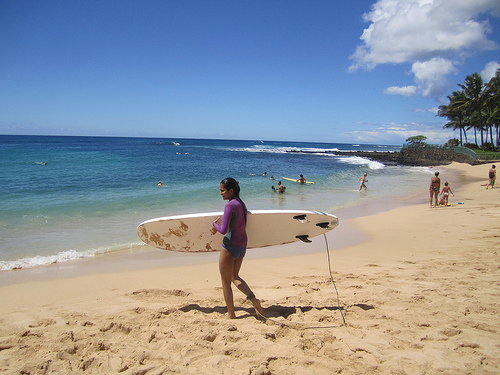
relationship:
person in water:
[151, 178, 167, 183] [25, 135, 132, 170]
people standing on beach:
[428, 171, 442, 208] [394, 205, 496, 251]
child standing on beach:
[441, 166, 458, 203] [394, 205, 496, 251]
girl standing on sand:
[211, 178, 263, 318] [2, 157, 499, 372]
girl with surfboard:
[211, 178, 263, 318] [137, 207, 340, 252]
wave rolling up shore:
[15, 225, 168, 287] [0, 150, 421, 315]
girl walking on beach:
[211, 178, 263, 318] [1, 153, 498, 373]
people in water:
[243, 158, 461, 199] [2, 139, 407, 257]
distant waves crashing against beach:
[48, 131, 104, 311] [85, 105, 180, 232]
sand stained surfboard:
[308, 245, 434, 320] [127, 197, 347, 270]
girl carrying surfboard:
[211, 178, 263, 318] [172, 203, 198, 338]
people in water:
[37, 160, 377, 200] [2, 133, 403, 266]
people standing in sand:
[430, 167, 453, 209] [18, 207, 499, 371]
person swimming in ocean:
[158, 180, 169, 187] [0, 135, 400, 272]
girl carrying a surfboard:
[211, 178, 263, 318] [137, 207, 340, 252]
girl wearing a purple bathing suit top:
[211, 178, 263, 318] [226, 193, 239, 247]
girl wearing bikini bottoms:
[211, 178, 263, 318] [221, 238, 256, 263]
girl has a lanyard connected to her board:
[222, 219, 246, 325] [136, 209, 339, 253]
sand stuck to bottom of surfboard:
[0, 226, 498, 370] [132, 191, 457, 235]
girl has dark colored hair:
[211, 178, 263, 318] [219, 146, 266, 259]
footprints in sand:
[370, 324, 395, 336] [2, 157, 499, 372]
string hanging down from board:
[306, 228, 335, 326] [133, 206, 339, 255]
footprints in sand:
[187, 273, 422, 345] [127, 306, 367, 375]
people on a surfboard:
[428, 171, 442, 208] [137, 207, 340, 252]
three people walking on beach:
[392, 157, 499, 304] [1, 153, 498, 373]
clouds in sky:
[346, 6, 499, 142] [3, 3, 497, 147]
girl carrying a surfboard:
[211, 178, 263, 318] [128, 207, 343, 257]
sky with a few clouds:
[3, 3, 497, 147] [307, 54, 424, 144]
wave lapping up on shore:
[0, 238, 139, 275] [2, 154, 498, 369]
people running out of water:
[358, 172, 368, 191] [281, 156, 406, 212]